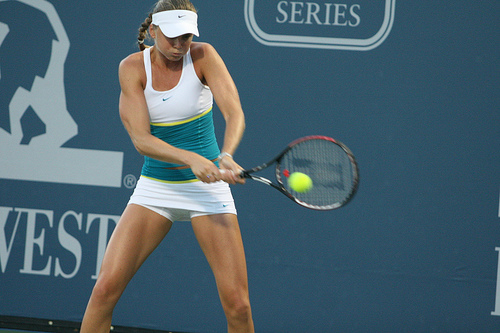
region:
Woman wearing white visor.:
[146, 5, 241, 48]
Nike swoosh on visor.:
[171, 9, 189, 21]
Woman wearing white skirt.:
[125, 152, 247, 244]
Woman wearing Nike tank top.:
[140, 68, 228, 185]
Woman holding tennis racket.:
[179, 162, 409, 192]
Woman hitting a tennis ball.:
[201, 127, 335, 219]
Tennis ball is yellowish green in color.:
[281, 165, 318, 200]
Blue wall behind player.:
[286, 104, 417, 247]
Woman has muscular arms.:
[103, 45, 192, 222]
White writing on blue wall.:
[17, 74, 123, 225]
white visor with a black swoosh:
[151, 8, 197, 35]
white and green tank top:
[141, 45, 216, 160]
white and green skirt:
[121, 157, 232, 212]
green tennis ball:
[289, 170, 312, 194]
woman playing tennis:
[77, 2, 259, 332]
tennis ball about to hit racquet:
[243, 134, 360, 212]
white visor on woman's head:
[147, 0, 199, 61]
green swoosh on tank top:
[160, 93, 174, 102]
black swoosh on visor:
[175, 11, 185, 17]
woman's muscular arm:
[114, 49, 218, 186]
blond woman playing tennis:
[100, 2, 370, 292]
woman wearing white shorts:
[112, 170, 252, 240]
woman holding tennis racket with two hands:
[186, 140, 369, 219]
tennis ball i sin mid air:
[277, 162, 327, 227]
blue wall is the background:
[351, 96, 449, 316]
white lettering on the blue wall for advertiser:
[11, 33, 89, 294]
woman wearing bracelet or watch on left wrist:
[214, 149, 247, 169]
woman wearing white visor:
[139, 7, 206, 73]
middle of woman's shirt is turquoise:
[125, 118, 217, 178]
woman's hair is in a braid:
[128, 7, 149, 59]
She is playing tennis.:
[115, 6, 377, 326]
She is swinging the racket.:
[118, 13, 374, 288]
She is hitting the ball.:
[103, 7, 365, 311]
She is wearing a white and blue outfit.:
[100, 13, 260, 331]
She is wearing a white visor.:
[110, 2, 235, 87]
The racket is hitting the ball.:
[211, 139, 403, 228]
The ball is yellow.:
[273, 164, 317, 199]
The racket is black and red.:
[207, 142, 389, 224]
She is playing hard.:
[72, 3, 383, 328]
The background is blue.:
[390, 89, 482, 293]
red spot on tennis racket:
[278, 164, 293, 179]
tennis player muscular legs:
[113, 221, 162, 275]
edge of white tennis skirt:
[153, 193, 197, 213]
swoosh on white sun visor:
[165, 13, 211, 33]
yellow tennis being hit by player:
[270, 166, 319, 201]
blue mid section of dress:
[128, 110, 250, 199]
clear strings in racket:
[285, 149, 376, 205]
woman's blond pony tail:
[127, 14, 182, 56]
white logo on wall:
[234, 7, 414, 91]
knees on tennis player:
[72, 265, 284, 318]